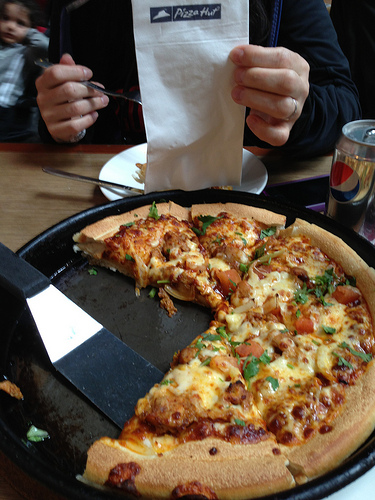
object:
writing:
[149, 5, 222, 20]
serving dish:
[0, 202, 375, 500]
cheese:
[104, 213, 374, 453]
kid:
[0, 0, 51, 143]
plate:
[97, 143, 267, 202]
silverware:
[34, 59, 143, 107]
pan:
[0, 186, 374, 500]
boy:
[35, 0, 362, 159]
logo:
[329, 161, 361, 205]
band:
[284, 99, 298, 121]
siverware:
[40, 165, 145, 194]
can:
[324, 120, 375, 242]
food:
[74, 201, 375, 500]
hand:
[228, 42, 310, 146]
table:
[2, 143, 374, 500]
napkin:
[129, 0, 247, 194]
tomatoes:
[297, 313, 314, 333]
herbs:
[294, 266, 341, 307]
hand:
[35, 53, 109, 142]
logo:
[149, 7, 170, 23]